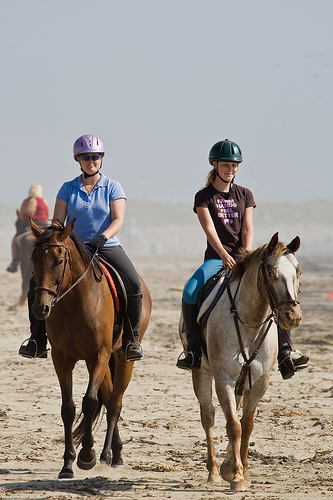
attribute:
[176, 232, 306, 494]
horse — brown, white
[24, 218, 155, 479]
horse — brown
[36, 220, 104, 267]
mane — black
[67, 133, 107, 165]
helmet — purple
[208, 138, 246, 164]
helmet — green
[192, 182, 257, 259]
t-shirt — black, brown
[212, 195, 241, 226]
letters — pink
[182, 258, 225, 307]
pants — blue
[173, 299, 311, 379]
boots — black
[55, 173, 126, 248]
shirt — blue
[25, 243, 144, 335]
pants — black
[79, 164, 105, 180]
strap — black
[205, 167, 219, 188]
hair — blonde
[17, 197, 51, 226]
shirt — red